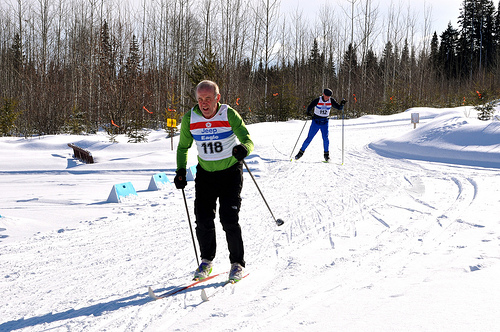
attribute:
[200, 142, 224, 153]
number — 118, black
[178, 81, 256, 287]
person — skating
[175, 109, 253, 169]
sweater — green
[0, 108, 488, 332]
trail — snow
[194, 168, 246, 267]
pants — black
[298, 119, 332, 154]
pants — blue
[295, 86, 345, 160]
person — skating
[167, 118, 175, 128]
sign — yellow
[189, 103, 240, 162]
vest — white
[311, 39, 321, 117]
tree — bare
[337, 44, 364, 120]
tree — bare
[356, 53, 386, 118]
tree — bare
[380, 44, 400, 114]
tree — bare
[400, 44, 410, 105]
tree — bare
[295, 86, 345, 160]
skiier — skiing, older man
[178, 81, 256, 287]
skiier — old, skiing, older man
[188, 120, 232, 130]
stripe — red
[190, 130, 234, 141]
stripe — blue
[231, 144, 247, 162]
glove — black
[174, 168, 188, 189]
glove — black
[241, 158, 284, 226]
skiing pole — black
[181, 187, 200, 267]
skiing pole — black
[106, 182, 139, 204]
trail marker — blue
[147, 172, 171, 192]
trail marker — blue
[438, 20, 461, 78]
tree — pine, large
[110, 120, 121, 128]
flag — orange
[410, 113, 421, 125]
sign — white, small, brown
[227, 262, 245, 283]
shoe — white, gray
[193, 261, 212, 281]
shoe — white, gray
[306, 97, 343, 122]
sweater — black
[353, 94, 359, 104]
flag — orange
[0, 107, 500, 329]
ground — white, snowy